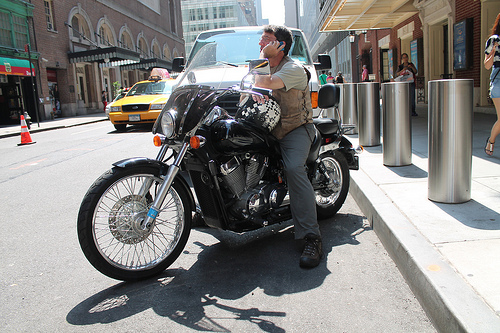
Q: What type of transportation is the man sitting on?
A: A motorcycle.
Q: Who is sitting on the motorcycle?
A: A man.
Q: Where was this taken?
A: A city street.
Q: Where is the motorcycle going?
A: Nowhere it's parked.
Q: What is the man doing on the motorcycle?
A: Sitting and talking on a phone.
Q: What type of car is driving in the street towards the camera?
A: A taxi.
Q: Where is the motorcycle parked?
A: On the side of the street.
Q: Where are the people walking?
A: On the sidewalk.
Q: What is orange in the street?
A: A traffic cone.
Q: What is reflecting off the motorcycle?
A: Sunlight.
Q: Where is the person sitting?
A: On bike.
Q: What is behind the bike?
A: Building.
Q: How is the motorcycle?
A: A black and chrome.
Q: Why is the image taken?
A: Remembrance.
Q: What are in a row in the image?
A: Metal canisters.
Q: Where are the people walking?
A: Sidewalk.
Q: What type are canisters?
A: Metal.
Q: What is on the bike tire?
A: Spokes.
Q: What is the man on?
A: A motorcycle.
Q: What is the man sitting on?
A: A motorcycle.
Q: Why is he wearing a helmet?
A: To protect his head.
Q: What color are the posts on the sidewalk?
A: Silver.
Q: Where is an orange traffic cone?
A: On the far left in the street.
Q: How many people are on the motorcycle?
A: 1.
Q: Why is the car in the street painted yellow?
A: It is a taxi cab.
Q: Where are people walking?
A: On the sidewalk.